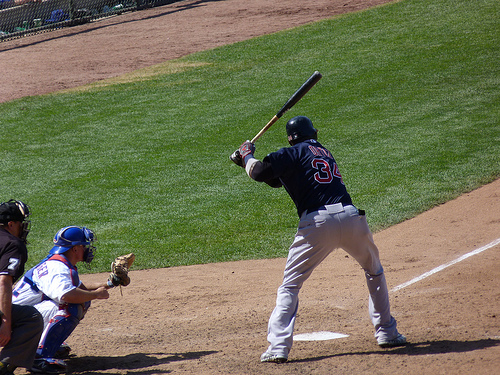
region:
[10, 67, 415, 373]
People playing baseball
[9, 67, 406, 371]
Men are playing baseball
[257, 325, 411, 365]
Man is wearing shoes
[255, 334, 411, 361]
Man is wearing white shoes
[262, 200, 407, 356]
Man is wearing pants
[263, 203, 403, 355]
Man is wearing white pants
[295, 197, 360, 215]
Man is wearing a belt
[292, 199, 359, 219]
Man is wearing a black belt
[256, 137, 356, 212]
Man is wearing a shirt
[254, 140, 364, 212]
Man is wearing a blue shirt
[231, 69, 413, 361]
man holding a bat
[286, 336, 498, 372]
man's shadow on the ground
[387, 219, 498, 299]
white line on the ground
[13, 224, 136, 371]
catcher squatting behind the batter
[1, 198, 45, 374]
umpire behind the catcher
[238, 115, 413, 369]
man wearing dark helmet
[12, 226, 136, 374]
catcher with baseball glove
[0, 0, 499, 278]
green grass on field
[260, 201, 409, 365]
batter wearing white pants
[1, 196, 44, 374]
umpire wearing black shirt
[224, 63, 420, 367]
A man playing baseball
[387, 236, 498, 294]
White line on the dirt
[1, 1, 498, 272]
Green grass on the field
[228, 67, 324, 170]
Baseball bat made of wood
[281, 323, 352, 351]
Home plate on the dirt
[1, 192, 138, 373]
Umpire behind the catcher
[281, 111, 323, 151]
Helmet on batter's head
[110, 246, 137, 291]
A brown leather glove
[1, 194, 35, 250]
Umpire wearing a face mask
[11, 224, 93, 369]
Catcher wearing a white uniform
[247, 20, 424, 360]
man swinging baseball bat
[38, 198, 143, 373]
catcher behind batter on mound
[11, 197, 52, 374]
umpire behind catcher on mound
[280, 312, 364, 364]
white home plate below batter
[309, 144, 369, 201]
number 34 on man's jersey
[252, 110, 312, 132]
black helmet on batter's head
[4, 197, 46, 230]
black helmet on umpire's head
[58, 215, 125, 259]
blue helmet on catcher's head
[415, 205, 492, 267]
white line on clay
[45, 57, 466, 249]
short green grass on field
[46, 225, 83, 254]
a blue baseball cap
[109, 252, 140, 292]
a brown baseball glove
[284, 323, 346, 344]
a white base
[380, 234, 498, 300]
a long white line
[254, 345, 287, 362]
the shoe of a man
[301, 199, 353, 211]
a man's black belt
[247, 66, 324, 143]
a brown and black bat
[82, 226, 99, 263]
a face mask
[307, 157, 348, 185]
a player's team number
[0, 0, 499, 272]
a section of green grass